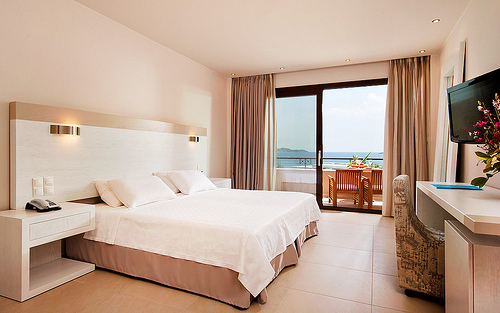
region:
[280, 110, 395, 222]
Water view in the hotel room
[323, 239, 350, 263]
Tile floor in the room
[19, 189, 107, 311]
Nightstand next to the bed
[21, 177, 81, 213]
Phone on the nightstand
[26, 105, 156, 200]
Light on the bed headboard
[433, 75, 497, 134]
Flat screen television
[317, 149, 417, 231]
Patio furniture on the patio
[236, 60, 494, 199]
Curtains on the windows and sliding door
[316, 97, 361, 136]
Nice day at the beach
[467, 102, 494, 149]
Flowers on the desk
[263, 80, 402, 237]
Ocean view from the room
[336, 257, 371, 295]
Tile floor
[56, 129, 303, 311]
A bed in the hotel room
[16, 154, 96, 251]
Nightstand next to the bed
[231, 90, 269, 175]
Curtains in the hotel room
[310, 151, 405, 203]
Patio outside the hotel room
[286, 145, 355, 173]
Water view from the room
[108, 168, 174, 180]
Pillows on the bed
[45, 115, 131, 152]
Lights on the bed's headboard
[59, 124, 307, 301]
a white bed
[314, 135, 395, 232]
brown wooden chairs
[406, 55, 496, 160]
a black flat screen tv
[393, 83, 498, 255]
flowers on a desk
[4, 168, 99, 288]
a white bedside table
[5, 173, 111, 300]
a white bedside table with a phone on it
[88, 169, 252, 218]
white pillows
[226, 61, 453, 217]
a balcony outside the bedroom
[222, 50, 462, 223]
tan curtains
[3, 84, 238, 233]
a white and tan headboard in back of the bed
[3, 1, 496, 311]
The room looks very clean.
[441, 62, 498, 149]
The television is hanging on the wall.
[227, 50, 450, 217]
There are curtains hanging up.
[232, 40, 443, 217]
The curtains are pulled open.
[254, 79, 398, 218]
There's sliding glass doors.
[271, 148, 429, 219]
Sliding doors lead to balcony.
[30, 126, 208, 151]
Lights hanging over the bed.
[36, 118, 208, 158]
Lights are turned on.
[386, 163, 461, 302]
There's a chair pushed up to desk area.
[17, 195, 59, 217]
There's a telephone beside the bed.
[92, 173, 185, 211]
two white pillows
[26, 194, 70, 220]
a telephone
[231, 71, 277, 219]
a curtain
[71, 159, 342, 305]
a king size bed with the sheets made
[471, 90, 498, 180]
some flowers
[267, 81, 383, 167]
a view of the ocean from the window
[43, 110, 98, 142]
a light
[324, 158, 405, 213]
two wooden outdoor chairs side by side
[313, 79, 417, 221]
a sliding glass door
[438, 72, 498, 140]
a tv screen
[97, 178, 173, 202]
pillows on the bed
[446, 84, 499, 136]
a television on the wall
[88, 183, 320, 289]
a large white bed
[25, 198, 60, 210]
a telephone on a desk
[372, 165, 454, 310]
beige and brown couch under counter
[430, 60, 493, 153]
flat screen on wall